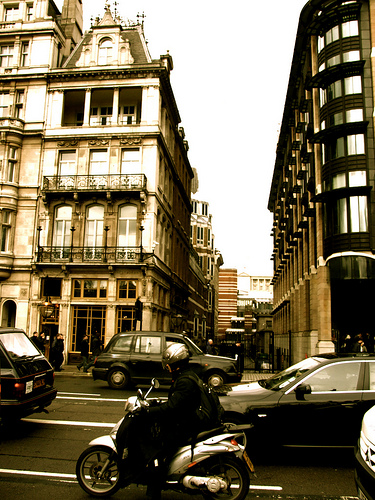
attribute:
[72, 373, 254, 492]
motorcycle — silver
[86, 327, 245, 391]
car — parked, black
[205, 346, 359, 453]
car — black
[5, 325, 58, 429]
car — black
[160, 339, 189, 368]
helmet — black, protective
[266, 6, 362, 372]
building — tall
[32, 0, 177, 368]
building — tall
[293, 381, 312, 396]
mirror — car, driver, side, rear, view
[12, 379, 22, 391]
light — car, red, brake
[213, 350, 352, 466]
car — black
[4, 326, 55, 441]
car — black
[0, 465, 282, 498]
line — white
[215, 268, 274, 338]
buildings — tall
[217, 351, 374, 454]
car — black